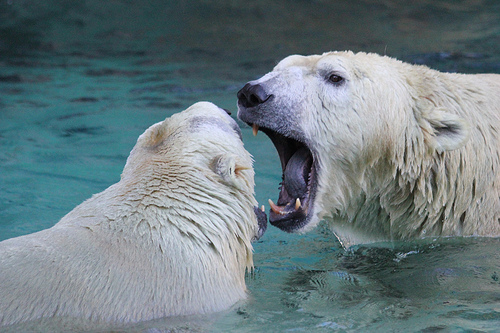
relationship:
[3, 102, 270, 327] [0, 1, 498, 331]
bear on water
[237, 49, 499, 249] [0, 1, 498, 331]
bear emerged water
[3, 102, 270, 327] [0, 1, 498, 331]
bear emerged water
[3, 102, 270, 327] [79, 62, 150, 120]
bear in water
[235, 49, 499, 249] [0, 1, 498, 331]
bear in water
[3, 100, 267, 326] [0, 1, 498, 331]
bear in water